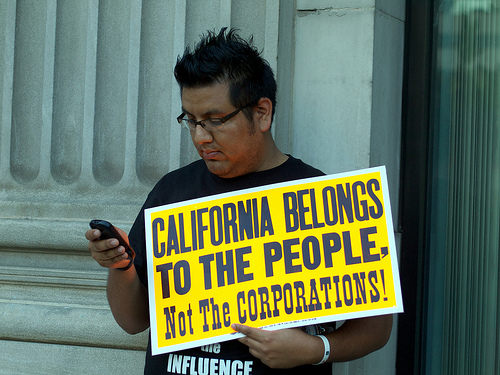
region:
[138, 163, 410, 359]
yellow rectangular protest sign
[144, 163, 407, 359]
yellow sign with black letters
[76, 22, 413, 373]
adult male looking at phone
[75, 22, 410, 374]
man holding protest sign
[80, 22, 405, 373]
man with black hair and glasses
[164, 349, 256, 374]
INFLUENCE in white letters on shirt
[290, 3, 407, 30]
crack in stone pillar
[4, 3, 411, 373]
stone wall behind man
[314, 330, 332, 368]
white bracelet on left wrist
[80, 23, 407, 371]
man with head tilted downward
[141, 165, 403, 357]
yellow protest sign with blue letters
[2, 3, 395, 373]
cement wall behind the man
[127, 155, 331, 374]
black t-shirt with white writing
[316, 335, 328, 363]
a white wristband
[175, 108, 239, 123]
the man's eyeglasses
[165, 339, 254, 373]
white text on the t-shirt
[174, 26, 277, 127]
the man's black, spiked hair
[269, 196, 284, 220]
the sign is yellow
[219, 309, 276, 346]
he is holding the sign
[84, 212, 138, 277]
he is holding the phone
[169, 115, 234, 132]
he is wearing glasses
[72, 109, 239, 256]
he is looking at the phone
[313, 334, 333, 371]
he is wearing a bracelet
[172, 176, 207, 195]
the shitr is black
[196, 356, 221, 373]
the word are white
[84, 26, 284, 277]
A man looking at his cell phone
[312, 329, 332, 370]
White bracelet around a wrist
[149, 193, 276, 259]
"CALIFORNIA" written on a sign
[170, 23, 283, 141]
Black hair on man's head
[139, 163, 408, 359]
A yellow sign with a white border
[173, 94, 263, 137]
A pair of eyeglasses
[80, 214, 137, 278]
Black cell phone in a hand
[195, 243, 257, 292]
The word "THE" on a sign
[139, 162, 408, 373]
A sign in a hand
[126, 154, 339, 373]
The shirt is black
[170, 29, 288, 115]
short black hair in a spiky style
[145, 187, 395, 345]
yellow protest sign against corprations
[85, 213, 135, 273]
mans hand holding a smartphone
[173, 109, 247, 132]
a pair of rimless eye glasses with heavy black side bars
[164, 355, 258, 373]
The word "influence" written in white letters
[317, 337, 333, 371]
white rubber cause armband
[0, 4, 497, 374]
the facade of what looks like a government building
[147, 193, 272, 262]
the word "California" on a protest sign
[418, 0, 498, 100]
patch of light hitting the building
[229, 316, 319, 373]
mans hand holding a yellow worded sign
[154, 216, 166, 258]
A letter on a sign.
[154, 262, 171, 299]
A letter on a sign.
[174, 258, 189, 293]
A letter on a sign.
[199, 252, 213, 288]
A letter on a sign.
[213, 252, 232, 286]
A letter on a sign.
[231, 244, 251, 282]
A letter on a sign.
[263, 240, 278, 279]
A letter on a sign.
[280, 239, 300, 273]
A letter on a sign.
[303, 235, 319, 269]
A letter on a sign.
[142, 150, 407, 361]
white yellow and purple sign